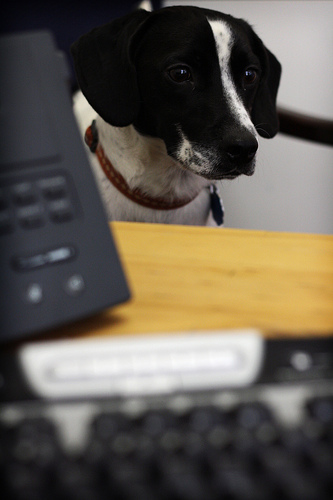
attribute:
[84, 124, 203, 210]
dog collar — Cloth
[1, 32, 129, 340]
office phone — Blurry, black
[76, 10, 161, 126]
dog ear — Black, furry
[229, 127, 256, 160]
dog nose — Black, wet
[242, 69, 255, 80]
dog eye — dark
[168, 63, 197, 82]
dog eye — dark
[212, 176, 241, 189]
whiskers — Small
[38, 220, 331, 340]
desk top — wooden, brown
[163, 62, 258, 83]
eyes — black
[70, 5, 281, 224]
dog — Black, white, medium sized, brown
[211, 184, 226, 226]
dog tag — silver, metal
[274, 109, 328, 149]
moulding — black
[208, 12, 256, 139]
stripe — white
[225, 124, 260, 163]
dog nose — large, black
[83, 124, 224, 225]
collar — red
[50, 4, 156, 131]
ear — black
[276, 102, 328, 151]
baseboard — brown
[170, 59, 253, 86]
eyes — brown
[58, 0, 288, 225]
dog — standing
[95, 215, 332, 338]
desk — brown, wooden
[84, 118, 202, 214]
collar — red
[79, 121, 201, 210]
collar — brown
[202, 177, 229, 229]
tag — silver, attached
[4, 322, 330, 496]
keyboard — Black, out of focus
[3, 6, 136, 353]
phone — grey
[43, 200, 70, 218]
button — black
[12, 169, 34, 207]
button — black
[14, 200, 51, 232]
button — black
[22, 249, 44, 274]
button — black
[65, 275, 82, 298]
button — black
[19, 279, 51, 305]
button — black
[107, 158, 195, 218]
collar — red